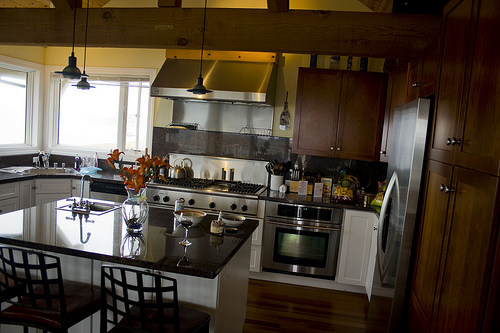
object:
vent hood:
[148, 58, 276, 109]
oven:
[260, 197, 345, 279]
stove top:
[148, 173, 265, 199]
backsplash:
[166, 152, 272, 187]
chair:
[0, 244, 106, 332]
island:
[2, 194, 259, 331]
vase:
[118, 184, 150, 233]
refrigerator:
[366, 97, 432, 333]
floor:
[241, 275, 369, 332]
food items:
[327, 180, 356, 204]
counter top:
[263, 186, 376, 213]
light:
[185, 1, 214, 98]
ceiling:
[2, 1, 449, 63]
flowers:
[105, 149, 128, 191]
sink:
[62, 195, 119, 217]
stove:
[142, 156, 265, 270]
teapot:
[163, 158, 191, 183]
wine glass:
[176, 210, 196, 247]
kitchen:
[0, 0, 498, 332]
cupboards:
[290, 67, 342, 158]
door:
[261, 219, 343, 279]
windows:
[55, 77, 123, 154]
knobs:
[240, 206, 248, 214]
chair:
[95, 264, 211, 333]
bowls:
[172, 208, 207, 228]